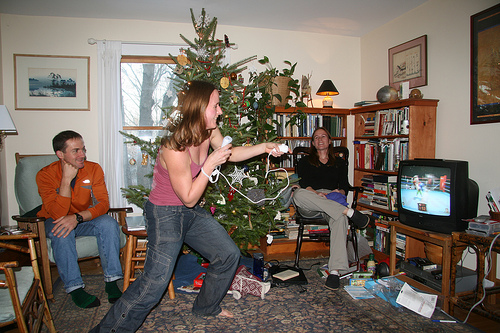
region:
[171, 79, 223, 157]
girl has brown hair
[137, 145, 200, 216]
girl has pink shirt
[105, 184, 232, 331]
girl has blue pants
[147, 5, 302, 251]
green tree behind girl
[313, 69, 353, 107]
black lamp on shelf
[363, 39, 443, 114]
red picture on wall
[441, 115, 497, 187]
white wall behind tv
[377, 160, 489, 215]
black case on tv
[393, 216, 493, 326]
tv on brown desk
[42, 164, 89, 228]
man has orange shirt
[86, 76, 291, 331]
THIS IS A LADY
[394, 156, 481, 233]
THIS IS A TELEVISION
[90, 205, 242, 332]
THESE ARE HER BLUE JEANS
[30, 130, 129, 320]
THIS IS A MAN SITTING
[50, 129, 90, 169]
THIS IS HIS HEAD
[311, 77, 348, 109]
THIS IS A LAMP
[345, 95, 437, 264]
THIS IS A BOOKCASE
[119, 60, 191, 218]
THIS IS A WINDOW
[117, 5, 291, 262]
THIS IS A CHRISTMAS TREE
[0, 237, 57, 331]
THIS IS A CHAIR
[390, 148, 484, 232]
A black television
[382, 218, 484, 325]
A wooden small television stand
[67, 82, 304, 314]
A woman holding a wii controller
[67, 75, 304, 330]
A woman standing up playing wii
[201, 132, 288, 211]
A white wii controller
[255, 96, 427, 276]
Two bookcases against the wall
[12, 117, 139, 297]
A man sitting in an armchair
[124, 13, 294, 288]
a Christmas tree with ornaments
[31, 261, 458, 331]
An area rug on the ground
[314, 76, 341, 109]
A small table lamp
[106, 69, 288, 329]
the girl holds the remote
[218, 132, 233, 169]
the remote in the hand of the girl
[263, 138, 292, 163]
the other handle of the control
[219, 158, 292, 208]
the white cord for the game controller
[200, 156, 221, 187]
the strap on the wrist of the girl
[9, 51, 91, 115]
the picture on the wall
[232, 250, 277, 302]
the presents under the tree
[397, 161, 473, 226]
the tv on the wooden stand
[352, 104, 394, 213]
the book shelf along the wall in the corner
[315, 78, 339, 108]
the lamp on top of the bookshelf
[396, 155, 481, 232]
a small black t.v.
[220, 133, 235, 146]
part of a white game controller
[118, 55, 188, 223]
part of a window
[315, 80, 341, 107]
a small table lamp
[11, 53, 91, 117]
a large brown picture frame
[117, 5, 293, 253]
a large green Christmas tree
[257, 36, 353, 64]
part of a painted wall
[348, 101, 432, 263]
a tall brown bookshelf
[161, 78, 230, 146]
a woman's long brown hair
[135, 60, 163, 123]
part of a tree branch